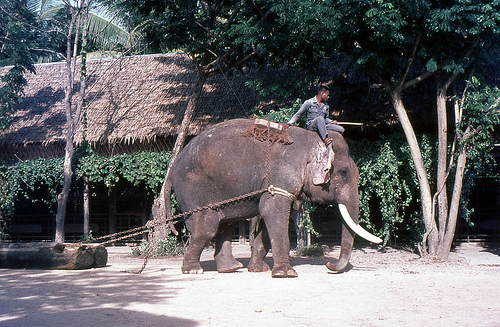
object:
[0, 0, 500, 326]
park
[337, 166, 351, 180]
eyes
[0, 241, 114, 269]
logs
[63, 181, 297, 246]
chain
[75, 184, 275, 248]
rope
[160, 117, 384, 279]
elephant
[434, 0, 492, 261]
tree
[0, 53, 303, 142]
roof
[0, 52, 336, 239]
building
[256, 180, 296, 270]
leg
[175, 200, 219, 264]
leg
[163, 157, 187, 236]
tail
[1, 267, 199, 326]
shadow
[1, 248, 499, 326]
road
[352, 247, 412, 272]
dirt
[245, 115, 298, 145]
saddle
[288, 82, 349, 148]
man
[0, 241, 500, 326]
ground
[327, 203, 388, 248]
tusk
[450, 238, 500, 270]
path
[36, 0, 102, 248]
palm tree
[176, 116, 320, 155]
back